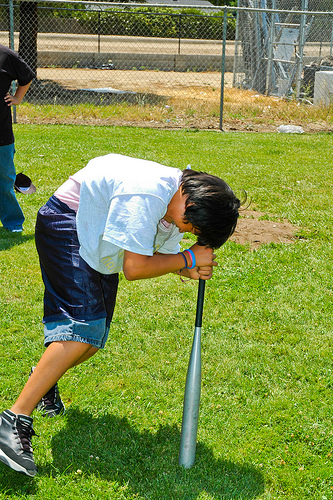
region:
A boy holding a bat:
[2, 148, 248, 482]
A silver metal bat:
[174, 272, 213, 471]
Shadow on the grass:
[1, 404, 265, 498]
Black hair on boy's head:
[167, 166, 249, 249]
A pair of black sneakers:
[0, 380, 67, 483]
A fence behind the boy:
[1, 0, 331, 130]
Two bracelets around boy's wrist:
[175, 242, 201, 273]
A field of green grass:
[1, 120, 330, 498]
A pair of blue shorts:
[32, 191, 119, 352]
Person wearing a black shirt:
[0, 43, 38, 146]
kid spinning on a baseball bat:
[9, 156, 240, 475]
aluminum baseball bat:
[180, 268, 212, 466]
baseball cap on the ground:
[13, 172, 35, 195]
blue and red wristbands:
[182, 246, 195, 268]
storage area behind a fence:
[228, 3, 331, 103]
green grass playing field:
[0, 126, 329, 494]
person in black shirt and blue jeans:
[0, 45, 33, 231]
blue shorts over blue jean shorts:
[39, 195, 118, 343]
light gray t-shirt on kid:
[78, 146, 183, 273]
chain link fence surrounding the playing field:
[3, 1, 331, 132]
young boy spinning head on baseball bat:
[0, 148, 251, 489]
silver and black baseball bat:
[174, 263, 208, 474]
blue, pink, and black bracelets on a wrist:
[173, 244, 198, 271]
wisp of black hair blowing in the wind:
[230, 188, 257, 214]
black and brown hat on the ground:
[12, 166, 38, 198]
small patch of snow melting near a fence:
[267, 117, 308, 138]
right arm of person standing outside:
[0, 45, 39, 111]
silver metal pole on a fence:
[215, 2, 233, 137]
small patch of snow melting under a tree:
[78, 82, 131, 98]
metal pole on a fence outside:
[92, 8, 105, 55]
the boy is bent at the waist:
[1, 154, 252, 496]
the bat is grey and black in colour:
[181, 290, 215, 482]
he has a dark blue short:
[29, 192, 113, 349]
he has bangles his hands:
[172, 238, 202, 280]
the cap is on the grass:
[12, 160, 44, 201]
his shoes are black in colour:
[1, 403, 54, 483]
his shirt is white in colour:
[93, 186, 147, 210]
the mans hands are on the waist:
[1, 21, 40, 195]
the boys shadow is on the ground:
[82, 394, 211, 497]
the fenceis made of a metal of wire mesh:
[83, 6, 204, 118]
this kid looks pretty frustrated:
[1, 149, 239, 479]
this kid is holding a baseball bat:
[178, 272, 208, 470]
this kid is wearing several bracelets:
[177, 248, 197, 270]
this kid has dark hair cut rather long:
[162, 165, 242, 247]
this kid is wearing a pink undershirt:
[50, 151, 181, 235]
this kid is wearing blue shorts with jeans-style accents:
[34, 192, 120, 346]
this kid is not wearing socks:
[1, 364, 67, 480]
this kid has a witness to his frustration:
[0, 40, 37, 235]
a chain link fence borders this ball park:
[2, 0, 331, 137]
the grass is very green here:
[2, 270, 331, 497]